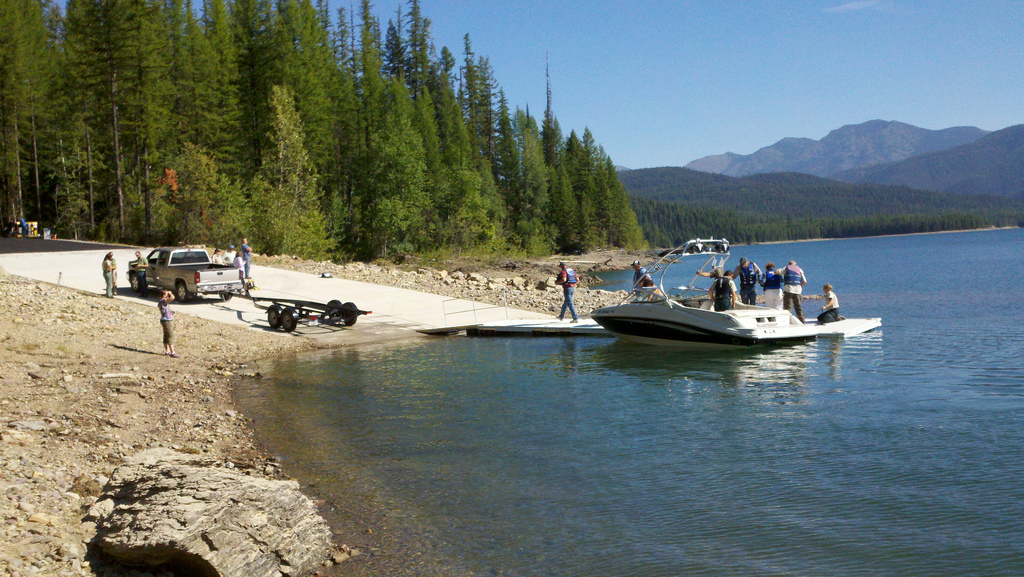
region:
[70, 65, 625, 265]
trees that are dark green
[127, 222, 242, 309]
a truck that is grey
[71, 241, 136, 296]
a person that is standing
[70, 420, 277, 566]
a large grey rock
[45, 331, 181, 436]
a big patch of brown dir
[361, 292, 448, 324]
a slab of bright white concrete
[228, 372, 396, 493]
the shore of a lake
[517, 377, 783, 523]
a bunch of ripples in the water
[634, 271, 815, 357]
a small white boat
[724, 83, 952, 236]
mountains in the distance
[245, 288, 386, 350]
an empty black boat trailer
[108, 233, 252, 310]
a two door, tan truck towing a trailer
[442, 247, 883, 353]
a small, floating boat dock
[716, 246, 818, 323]
a few people wearing life jackets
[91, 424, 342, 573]
a large rock on the beach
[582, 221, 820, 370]
a white and black speed boat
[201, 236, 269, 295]
people standing on a boat ramp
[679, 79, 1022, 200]
a mountain range in the distance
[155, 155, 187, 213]
a branch covered in brown leaves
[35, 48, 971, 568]
this is a harbor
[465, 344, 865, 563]
the water is blue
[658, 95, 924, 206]
the background is mountains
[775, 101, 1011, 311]
the mountains are brown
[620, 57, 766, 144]
the sky is clear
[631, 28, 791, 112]
the sky is white and blue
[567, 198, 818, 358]
this is a boat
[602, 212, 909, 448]
the boat is white and black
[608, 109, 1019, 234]
very large rocky mountains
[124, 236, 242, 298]
a pick up truck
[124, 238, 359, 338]
pick up truck with a towing trailer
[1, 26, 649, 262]
a forest of green trees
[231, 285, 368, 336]
a trailer hitch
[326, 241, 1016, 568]
water in a lake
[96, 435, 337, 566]
large stone by the shore line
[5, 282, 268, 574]
a shoreline of rocks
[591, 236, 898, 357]
a small white boat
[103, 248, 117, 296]
a person is standing up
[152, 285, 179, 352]
a person is standing up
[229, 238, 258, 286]
a person is standing up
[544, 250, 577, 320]
a person is standing up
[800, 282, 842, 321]
a person is sitting down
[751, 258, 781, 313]
a person is standing up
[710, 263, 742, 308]
a person is standing up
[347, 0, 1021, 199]
The clear blue sky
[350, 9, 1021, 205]
A clear blue sky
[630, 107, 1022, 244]
The mountain range in the background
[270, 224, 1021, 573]
A body of water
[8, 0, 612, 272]
The forest of trees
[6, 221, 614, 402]
A concrete ramp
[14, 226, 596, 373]
The concrete ramp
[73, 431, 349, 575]
a large rock near the water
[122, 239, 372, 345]
a truck with a trailer attached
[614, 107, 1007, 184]
a mountain range in the far distance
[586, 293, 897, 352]
a large boat in the water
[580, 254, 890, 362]
a large boat with people on it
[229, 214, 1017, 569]
a large body of water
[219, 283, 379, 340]
a boat trailer near the water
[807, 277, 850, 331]
a man wearing a white shirt on the end of the boat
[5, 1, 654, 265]
a group of trees on the shoreline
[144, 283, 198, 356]
a woman shading her eyes from the sun